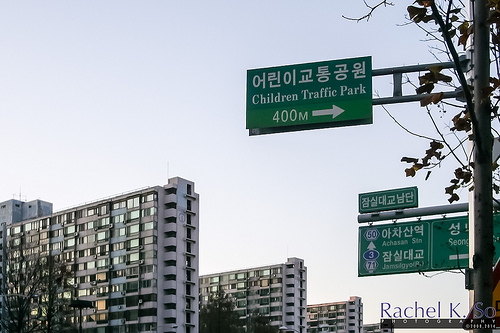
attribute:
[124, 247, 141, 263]
building window — residential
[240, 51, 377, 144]
sign — green, white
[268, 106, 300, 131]
white number — white 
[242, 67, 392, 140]
sign — green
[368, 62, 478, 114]
pole — grey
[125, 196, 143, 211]
window — residential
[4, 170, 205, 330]
building — large, residential, tall, white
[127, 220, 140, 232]
window — residential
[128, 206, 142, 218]
window — large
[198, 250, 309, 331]
building — residential, large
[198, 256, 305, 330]
building — residential, large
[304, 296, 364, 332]
building — residential, large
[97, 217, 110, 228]
window — large